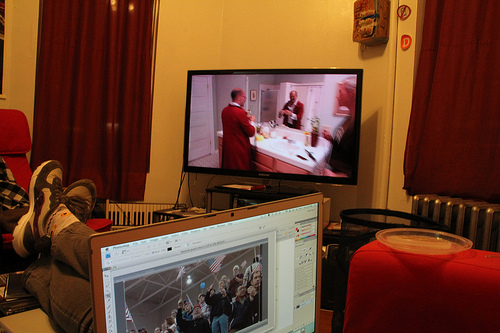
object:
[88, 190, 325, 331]
laptop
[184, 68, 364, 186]
television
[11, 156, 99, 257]
feet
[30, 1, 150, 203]
curtains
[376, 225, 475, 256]
plate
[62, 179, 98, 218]
sneakers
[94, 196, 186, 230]
keyboard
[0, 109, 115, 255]
chair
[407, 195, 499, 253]
radiator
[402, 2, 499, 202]
curtains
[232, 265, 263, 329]
people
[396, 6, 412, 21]
stickers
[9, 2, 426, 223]
wall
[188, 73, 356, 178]
bathroom scene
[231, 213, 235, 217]
webcam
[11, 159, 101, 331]
person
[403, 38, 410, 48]
letter d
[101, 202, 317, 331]
monitor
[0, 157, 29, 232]
fabric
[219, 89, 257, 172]
man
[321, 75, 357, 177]
woman